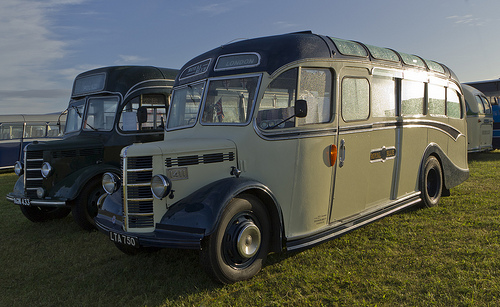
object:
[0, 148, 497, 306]
grass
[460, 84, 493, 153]
bus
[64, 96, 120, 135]
windshield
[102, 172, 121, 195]
headlight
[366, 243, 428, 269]
ground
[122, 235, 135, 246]
numbers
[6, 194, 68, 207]
front fender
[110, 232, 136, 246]
license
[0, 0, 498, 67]
sky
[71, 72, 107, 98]
sign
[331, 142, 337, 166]
light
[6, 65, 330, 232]
black vehicle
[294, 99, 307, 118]
rearview mirror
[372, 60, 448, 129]
shining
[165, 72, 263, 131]
window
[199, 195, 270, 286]
wheels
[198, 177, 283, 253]
fender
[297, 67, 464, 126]
passenger window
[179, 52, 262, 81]
sign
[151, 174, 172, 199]
car lights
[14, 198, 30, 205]
license plates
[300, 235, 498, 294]
field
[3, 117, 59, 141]
area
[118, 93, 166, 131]
window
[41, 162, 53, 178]
headlight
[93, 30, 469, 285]
bus